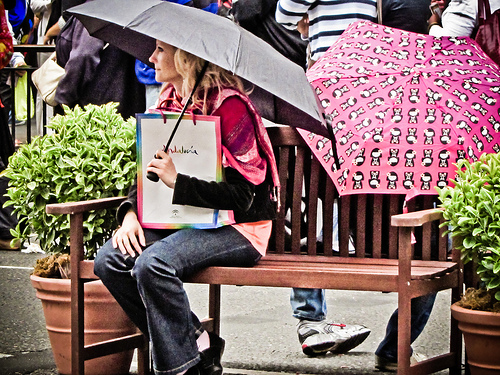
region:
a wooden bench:
[50, 128, 462, 370]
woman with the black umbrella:
[63, 5, 338, 374]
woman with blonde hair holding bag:
[93, 40, 273, 371]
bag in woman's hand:
[138, 108, 238, 228]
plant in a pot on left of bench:
[8, 104, 142, 373]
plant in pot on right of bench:
[446, 158, 498, 374]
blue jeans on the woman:
[93, 223, 260, 373]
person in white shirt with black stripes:
[275, 3, 378, 59]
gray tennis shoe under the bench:
[297, 320, 367, 352]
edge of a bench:
[302, 278, 331, 318]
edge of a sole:
[329, 345, 342, 356]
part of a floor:
[257, 311, 272, 336]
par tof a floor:
[262, 322, 276, 361]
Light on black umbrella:
[170, 15, 204, 39]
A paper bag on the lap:
[147, 208, 202, 224]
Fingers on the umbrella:
[152, 160, 172, 170]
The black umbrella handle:
[150, 174, 155, 178]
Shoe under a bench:
[303, 326, 360, 341]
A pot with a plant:
[87, 306, 114, 333]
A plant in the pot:
[26, 177, 111, 188]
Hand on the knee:
[118, 228, 140, 248]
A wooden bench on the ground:
[315, 258, 389, 283]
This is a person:
[60, 2, 282, 374]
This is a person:
[70, 12, 305, 370]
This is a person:
[83, 10, 293, 373]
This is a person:
[68, 12, 273, 367]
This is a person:
[71, 13, 297, 344]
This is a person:
[86, 18, 303, 366]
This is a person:
[75, 13, 290, 373]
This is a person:
[86, 14, 316, 370]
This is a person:
[97, 21, 310, 369]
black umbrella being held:
[68, 9, 353, 140]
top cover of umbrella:
[72, 0, 359, 137]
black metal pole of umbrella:
[158, 85, 190, 150]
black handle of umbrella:
[144, 159, 166, 183]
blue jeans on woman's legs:
[71, 221, 239, 368]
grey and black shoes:
[304, 319, 369, 349]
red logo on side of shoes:
[328, 315, 359, 330]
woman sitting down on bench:
[2, 9, 314, 363]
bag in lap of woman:
[117, 111, 235, 252]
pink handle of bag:
[147, 96, 201, 134]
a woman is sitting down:
[76, 30, 287, 367]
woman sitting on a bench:
[56, 51, 471, 373]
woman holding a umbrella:
[58, 0, 338, 204]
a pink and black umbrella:
[310, 19, 495, 205]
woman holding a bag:
[130, 100, 231, 232]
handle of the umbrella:
[145, 63, 211, 185]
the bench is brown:
[43, 108, 460, 374]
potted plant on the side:
[2, 93, 139, 371]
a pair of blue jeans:
[85, 219, 225, 368]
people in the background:
[6, 0, 478, 98]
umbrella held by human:
[63, 1, 330, 183]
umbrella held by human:
[292, 19, 499, 202]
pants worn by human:
[93, 197, 268, 374]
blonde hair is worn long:
[177, 44, 249, 109]